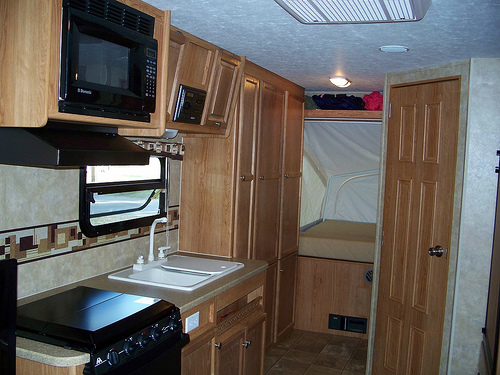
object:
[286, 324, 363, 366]
tile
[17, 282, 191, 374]
range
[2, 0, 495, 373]
kitchen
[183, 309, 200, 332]
outlet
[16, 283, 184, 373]
dishwasher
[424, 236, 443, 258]
doorknob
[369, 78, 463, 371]
closed door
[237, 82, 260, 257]
closed door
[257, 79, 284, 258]
closed door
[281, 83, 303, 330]
closed door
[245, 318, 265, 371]
closed door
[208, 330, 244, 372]
closed door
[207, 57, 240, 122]
closed door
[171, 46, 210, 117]
closed door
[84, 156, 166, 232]
window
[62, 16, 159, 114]
microwave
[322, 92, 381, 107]
clothes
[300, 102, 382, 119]
shelf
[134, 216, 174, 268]
faucet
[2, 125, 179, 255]
wall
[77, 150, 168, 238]
frame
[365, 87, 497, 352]
door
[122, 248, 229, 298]
sink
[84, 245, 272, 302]
counter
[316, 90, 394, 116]
bag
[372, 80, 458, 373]
brown door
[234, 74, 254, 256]
cabinet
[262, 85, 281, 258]
cabinet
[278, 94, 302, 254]
cabinet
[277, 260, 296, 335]
cabinet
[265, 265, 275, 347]
cabinet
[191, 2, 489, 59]
ceiling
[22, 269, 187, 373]
stove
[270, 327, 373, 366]
floor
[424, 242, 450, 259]
handle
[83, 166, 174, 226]
cover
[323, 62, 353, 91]
light